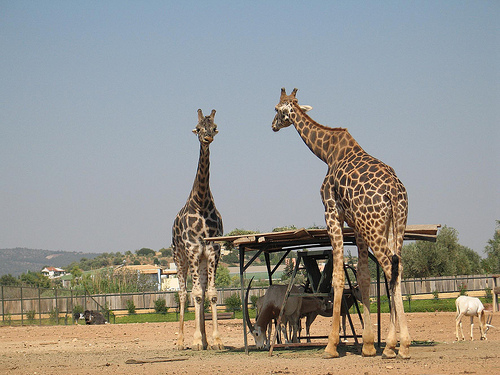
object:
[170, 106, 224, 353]
giraffe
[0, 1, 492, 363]
camera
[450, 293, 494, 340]
goat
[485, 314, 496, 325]
long horns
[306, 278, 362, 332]
goats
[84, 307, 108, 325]
black cow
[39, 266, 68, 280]
white house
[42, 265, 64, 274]
red roof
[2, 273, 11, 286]
trees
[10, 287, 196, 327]
fence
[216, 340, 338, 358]
dry grass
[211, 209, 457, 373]
structure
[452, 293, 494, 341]
gazelle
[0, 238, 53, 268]
hills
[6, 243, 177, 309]
distance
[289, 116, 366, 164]
neck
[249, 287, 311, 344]
antelopes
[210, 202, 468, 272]
shade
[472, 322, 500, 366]
food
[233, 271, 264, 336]
horn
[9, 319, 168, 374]
ground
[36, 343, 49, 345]
pebbles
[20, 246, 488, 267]
edge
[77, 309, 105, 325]
animal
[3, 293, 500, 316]
grass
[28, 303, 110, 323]
bush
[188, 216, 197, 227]
spots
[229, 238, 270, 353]
frame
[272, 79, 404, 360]
giraffes